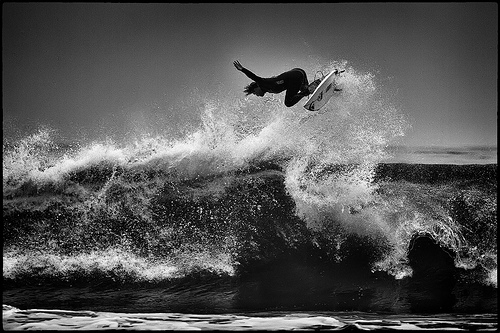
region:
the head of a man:
[233, 60, 283, 110]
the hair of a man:
[235, 75, 274, 108]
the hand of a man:
[221, 49, 247, 75]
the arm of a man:
[224, 47, 296, 111]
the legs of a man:
[268, 45, 344, 116]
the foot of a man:
[304, 75, 329, 101]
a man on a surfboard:
[234, 33, 384, 155]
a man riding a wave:
[159, 23, 446, 225]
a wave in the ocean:
[112, 2, 469, 244]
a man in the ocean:
[126, 18, 441, 240]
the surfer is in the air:
[206, 40, 418, 165]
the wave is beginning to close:
[21, 108, 492, 331]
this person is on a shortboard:
[200, 37, 390, 147]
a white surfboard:
[298, 53, 368, 130]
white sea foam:
[3, 303, 398, 331]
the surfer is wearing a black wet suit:
[216, 45, 366, 127]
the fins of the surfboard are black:
[337, 64, 357, 103]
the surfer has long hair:
[233, 66, 293, 106]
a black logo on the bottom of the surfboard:
[303, 82, 330, 114]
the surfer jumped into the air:
[193, 22, 393, 147]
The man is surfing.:
[234, 58, 349, 113]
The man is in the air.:
[233, 54, 347, 111]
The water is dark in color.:
[268, 255, 346, 305]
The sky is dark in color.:
[6, 4, 106, 61]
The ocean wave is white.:
[126, 141, 214, 206]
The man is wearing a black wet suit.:
[232, 58, 321, 110]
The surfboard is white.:
[304, 66, 346, 115]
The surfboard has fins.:
[304, 67, 349, 112]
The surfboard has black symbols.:
[306, 68, 349, 115]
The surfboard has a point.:
[304, 68, 350, 118]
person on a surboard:
[212, 48, 363, 120]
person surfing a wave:
[1, 10, 499, 308]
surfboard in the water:
[303, 66, 346, 120]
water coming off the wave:
[169, 84, 247, 144]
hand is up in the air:
[225, 56, 272, 86]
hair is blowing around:
[237, 78, 252, 98]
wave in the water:
[7, 63, 499, 283]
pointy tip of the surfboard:
[299, 96, 311, 113]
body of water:
[4, 126, 499, 331]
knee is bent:
[278, 92, 299, 109]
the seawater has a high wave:
[13, 125, 499, 316]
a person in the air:
[221, 47, 311, 106]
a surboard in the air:
[301, 65, 353, 116]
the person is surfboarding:
[228, 55, 350, 115]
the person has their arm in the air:
[226, 50, 315, 105]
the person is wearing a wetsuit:
[231, 62, 308, 104]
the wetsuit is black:
[229, 56, 306, 108]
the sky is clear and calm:
[20, 11, 498, 169]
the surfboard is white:
[294, 62, 346, 116]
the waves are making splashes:
[3, 75, 498, 312]